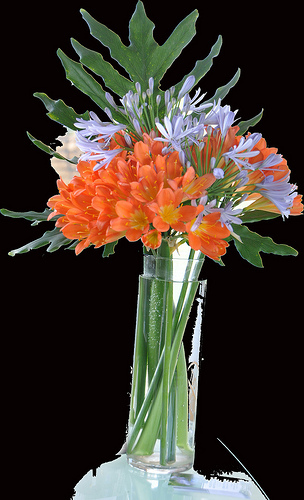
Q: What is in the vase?
A: Flowers.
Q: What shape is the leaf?
A: Finger shaped.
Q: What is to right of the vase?
A: Nothing.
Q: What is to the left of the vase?
A: Nothing.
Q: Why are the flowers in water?
A: To keep them fresh.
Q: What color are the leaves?
A: Green.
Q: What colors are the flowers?
A: Orange and purple.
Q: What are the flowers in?
A: A vase.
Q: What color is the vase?
A: Clear.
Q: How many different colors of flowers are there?
A: Two.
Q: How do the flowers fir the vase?
A: They are cut.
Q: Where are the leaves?
A: Behind the flowers.